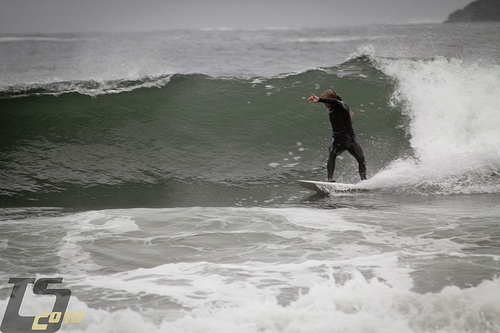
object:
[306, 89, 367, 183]
man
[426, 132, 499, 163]
wave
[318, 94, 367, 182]
wet suit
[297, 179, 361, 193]
surf board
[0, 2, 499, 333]
ocean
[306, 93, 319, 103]
left hand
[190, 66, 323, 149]
air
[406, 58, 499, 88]
water spray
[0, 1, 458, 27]
sky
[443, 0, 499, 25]
land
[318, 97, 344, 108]
arm